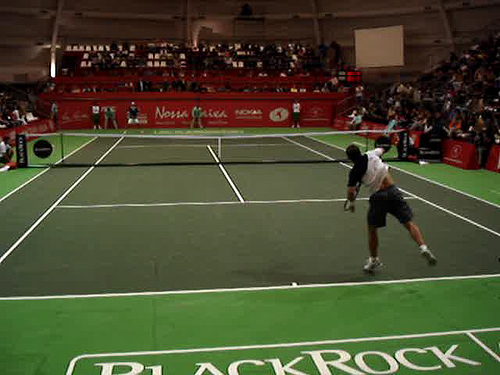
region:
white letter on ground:
[97, 356, 137, 373]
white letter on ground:
[144, 358, 164, 374]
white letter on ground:
[191, 357, 226, 374]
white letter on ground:
[228, 356, 265, 373]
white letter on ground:
[267, 353, 306, 373]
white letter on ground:
[301, 343, 361, 373]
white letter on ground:
[354, 348, 399, 373]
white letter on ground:
[394, 344, 441, 370]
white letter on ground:
[426, 336, 480, 367]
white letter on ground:
[101, 342, 483, 374]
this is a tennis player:
[318, 127, 428, 286]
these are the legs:
[360, 204, 437, 276]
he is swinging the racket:
[373, 115, 405, 150]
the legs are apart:
[357, 212, 429, 280]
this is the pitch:
[192, 160, 307, 262]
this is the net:
[225, 130, 272, 170]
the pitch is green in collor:
[323, 293, 378, 335]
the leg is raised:
[407, 218, 439, 267]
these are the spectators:
[200, 40, 272, 85]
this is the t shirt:
[361, 157, 386, 175]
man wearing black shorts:
[322, 114, 448, 263]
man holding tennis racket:
[310, 125, 435, 275]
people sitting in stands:
[46, 38, 343, 91]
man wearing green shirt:
[102, 106, 123, 137]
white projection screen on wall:
[344, 21, 409, 73]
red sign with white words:
[50, 88, 352, 130]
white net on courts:
[21, 125, 381, 170]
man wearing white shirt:
[289, 96, 310, 128]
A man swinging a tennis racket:
[340, 135, 439, 274]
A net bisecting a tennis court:
[13, 131, 414, 164]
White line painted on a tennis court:
[54, 199, 241, 216]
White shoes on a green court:
[364, 255, 382, 272]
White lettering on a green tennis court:
[83, 342, 477, 374]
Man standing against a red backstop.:
[288, 98, 302, 128]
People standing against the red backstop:
[90, 98, 116, 134]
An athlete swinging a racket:
[340, 136, 440, 274]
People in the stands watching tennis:
[365, 41, 499, 124]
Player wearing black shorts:
[366, 182, 415, 227]